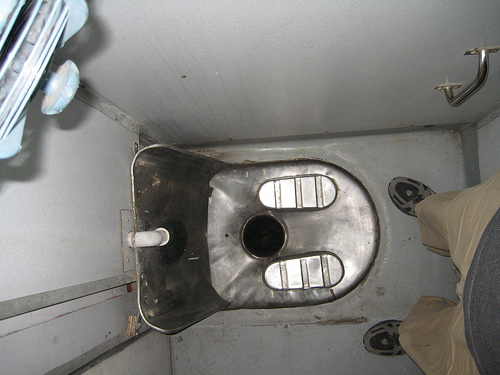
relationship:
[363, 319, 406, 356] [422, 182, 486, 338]
feet of person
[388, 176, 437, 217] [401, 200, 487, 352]
feet of person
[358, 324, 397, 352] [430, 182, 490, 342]
feet of person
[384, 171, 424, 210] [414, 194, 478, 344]
feet of person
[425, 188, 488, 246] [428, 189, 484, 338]
leg of person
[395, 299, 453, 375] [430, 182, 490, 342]
leg of person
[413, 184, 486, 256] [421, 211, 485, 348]
leg of person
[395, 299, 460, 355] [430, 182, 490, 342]
leg of person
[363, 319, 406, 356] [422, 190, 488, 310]
feet of person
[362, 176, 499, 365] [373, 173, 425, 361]
man wearing shoes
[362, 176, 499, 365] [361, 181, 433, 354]
man wearing shoes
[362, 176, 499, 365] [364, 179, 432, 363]
man wearing shoes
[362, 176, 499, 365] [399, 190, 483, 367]
man wearing pants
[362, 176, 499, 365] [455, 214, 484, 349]
man wearing shirt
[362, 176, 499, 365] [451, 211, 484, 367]
man wearing shirt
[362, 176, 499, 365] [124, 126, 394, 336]
man stands toilet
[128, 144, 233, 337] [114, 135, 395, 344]
lid of toilet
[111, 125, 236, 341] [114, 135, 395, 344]
lid of toilet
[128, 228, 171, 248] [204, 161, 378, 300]
pipe of lid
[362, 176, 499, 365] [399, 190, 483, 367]
man wears pants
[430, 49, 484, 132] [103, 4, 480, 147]
handle of door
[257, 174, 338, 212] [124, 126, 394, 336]
footprint on toilet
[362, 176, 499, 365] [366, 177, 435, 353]
man wearing shoes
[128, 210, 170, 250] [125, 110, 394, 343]
pipe coming toilet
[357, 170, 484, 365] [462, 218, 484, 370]
man wearing shirt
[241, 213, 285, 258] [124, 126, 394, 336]
hole in toilet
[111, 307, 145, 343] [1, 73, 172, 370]
piece on wall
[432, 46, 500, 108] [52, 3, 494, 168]
handle on wall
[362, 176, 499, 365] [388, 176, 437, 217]
man wearing feet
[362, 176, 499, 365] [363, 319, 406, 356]
man wearing feet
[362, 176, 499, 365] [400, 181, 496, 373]
man wearing pants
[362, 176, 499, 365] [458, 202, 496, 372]
man wearing shirt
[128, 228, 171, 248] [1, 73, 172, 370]
pipe on wall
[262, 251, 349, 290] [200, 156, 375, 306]
footprint on seat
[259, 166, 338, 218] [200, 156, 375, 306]
footprint on seat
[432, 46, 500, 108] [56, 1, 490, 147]
handle on door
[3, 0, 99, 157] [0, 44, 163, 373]
thing on wall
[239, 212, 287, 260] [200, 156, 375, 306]
hole on seat